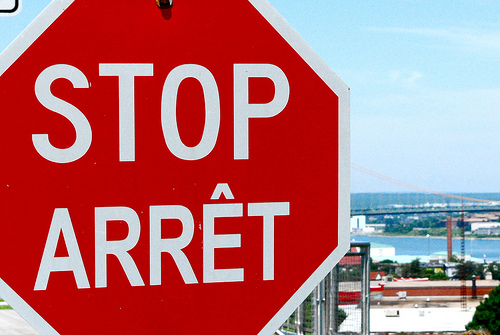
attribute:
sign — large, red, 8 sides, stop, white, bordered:
[1, 2, 355, 335]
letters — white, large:
[22, 62, 297, 294]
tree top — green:
[466, 283, 500, 330]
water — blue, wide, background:
[351, 229, 500, 265]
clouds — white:
[361, 17, 497, 53]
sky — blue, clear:
[1, 1, 500, 197]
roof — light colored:
[337, 302, 485, 331]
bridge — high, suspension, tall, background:
[345, 162, 500, 262]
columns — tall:
[446, 216, 455, 265]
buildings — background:
[356, 199, 500, 240]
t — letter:
[95, 58, 156, 168]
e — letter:
[197, 199, 245, 290]